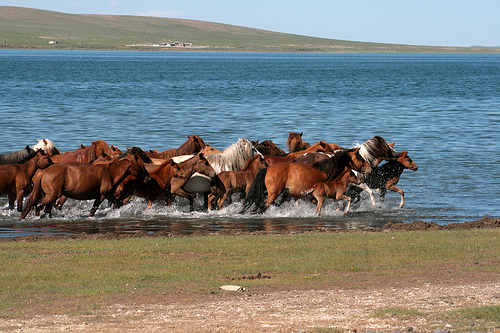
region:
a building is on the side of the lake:
[2, 2, 380, 72]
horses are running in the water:
[5, 114, 427, 262]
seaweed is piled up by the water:
[13, 211, 497, 251]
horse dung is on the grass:
[220, 265, 280, 290]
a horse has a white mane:
[206, 135, 262, 175]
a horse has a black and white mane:
[351, 130, 395, 170]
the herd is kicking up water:
[1, 178, 407, 238]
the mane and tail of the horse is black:
[239, 145, 360, 221]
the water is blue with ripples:
[3, 45, 495, 167]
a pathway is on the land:
[25, 275, 499, 331]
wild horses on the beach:
[0, 118, 425, 220]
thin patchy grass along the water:
[0, 235, 499, 315]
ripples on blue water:
[6, 53, 498, 130]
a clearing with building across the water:
[129, 36, 229, 53]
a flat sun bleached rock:
[216, 281, 246, 293]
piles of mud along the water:
[366, 211, 498, 236]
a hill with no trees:
[1, 3, 493, 48]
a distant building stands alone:
[48, 35, 58, 47]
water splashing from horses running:
[0, 197, 386, 217]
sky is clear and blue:
[127, 1, 499, 43]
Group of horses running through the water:
[0, 133, 428, 225]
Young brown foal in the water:
[302, 167, 364, 218]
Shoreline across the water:
[0, 45, 499, 57]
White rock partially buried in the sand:
[215, 280, 245, 294]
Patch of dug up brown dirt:
[224, 268, 272, 283]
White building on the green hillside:
[44, 36, 60, 46]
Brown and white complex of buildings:
[152, 38, 192, 48]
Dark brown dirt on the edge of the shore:
[369, 211, 499, 231]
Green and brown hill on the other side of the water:
[0, 2, 498, 50]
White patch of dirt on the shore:
[0, 280, 499, 332]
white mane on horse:
[218, 142, 251, 168]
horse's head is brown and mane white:
[338, 133, 394, 170]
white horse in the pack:
[187, 154, 247, 177]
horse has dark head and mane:
[7, 141, 41, 165]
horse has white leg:
[346, 171, 380, 210]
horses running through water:
[3, 130, 453, 231]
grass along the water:
[17, 222, 482, 268]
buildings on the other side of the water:
[33, 37, 234, 51]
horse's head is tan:
[194, 140, 226, 162]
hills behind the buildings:
[5, 5, 285, 38]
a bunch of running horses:
[21, 131, 413, 218]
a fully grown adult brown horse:
[251, 158, 361, 203]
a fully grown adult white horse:
[361, 139, 391, 160]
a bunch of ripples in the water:
[80, 71, 142, 121]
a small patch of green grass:
[127, 242, 172, 282]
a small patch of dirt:
[297, 276, 347, 323]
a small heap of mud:
[395, 205, 453, 229]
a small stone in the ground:
[204, 281, 259, 299]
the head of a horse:
[320, 132, 368, 169]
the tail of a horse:
[15, 171, 59, 202]